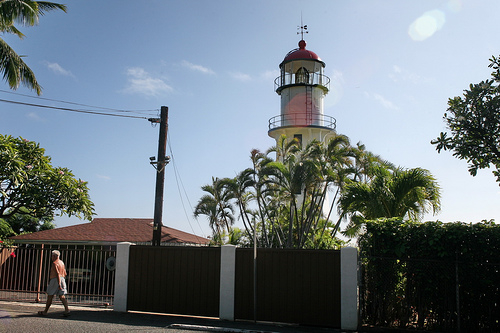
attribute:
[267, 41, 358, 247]
lighthouse — white, red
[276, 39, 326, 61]
roof — red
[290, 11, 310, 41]
weather vane — metal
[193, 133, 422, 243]
palm trees — young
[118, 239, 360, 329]
gate — brown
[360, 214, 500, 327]
hedge — eight feet, green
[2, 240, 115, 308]
gate — closed, steel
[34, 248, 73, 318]
person — walking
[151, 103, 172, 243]
pole — utility, wooden, telephone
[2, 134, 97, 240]
tree — healthy, green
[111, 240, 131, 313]
posts — white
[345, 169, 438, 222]
tree — palm, green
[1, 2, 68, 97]
tree — green, healthy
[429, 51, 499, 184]
tree — green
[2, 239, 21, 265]
something — red